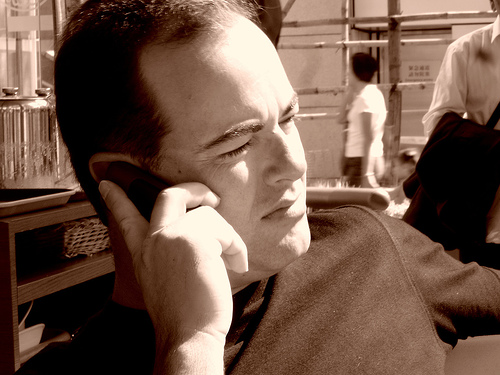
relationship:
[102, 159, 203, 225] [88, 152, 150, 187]
cell phone pressed against ear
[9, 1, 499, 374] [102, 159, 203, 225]
man using cell phone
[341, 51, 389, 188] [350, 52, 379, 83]
person wearing hat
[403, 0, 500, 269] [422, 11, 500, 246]
person wearing shirt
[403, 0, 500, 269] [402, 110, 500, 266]
person carrying coat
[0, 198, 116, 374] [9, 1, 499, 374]
shelf behind man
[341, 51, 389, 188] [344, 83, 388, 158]
person wearing shirt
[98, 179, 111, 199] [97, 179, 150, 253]
fingernail on top of finger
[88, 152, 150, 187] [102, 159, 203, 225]
ear beneath cell phone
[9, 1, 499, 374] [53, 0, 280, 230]
man has hair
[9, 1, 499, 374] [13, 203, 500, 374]
man has shirt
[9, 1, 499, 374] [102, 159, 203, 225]
man holding cell phone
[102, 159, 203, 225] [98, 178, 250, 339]
cell phone in hand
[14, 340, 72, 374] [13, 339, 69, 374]
back of chair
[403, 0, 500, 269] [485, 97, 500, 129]
person has bag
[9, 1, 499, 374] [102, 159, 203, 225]
man talking on cell phone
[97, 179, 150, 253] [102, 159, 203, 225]
finger on cell phone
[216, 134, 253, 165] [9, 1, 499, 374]
eye of man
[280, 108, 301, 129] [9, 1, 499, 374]
eye of man